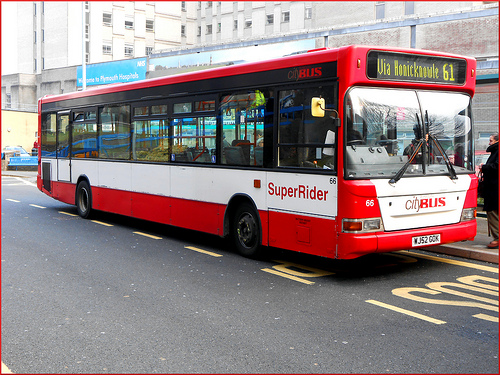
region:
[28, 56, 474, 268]
Large red and white city bus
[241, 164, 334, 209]
Bus has SuperRider printed on side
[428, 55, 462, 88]
Bus number is 61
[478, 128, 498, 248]
Person at bus stop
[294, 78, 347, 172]
Rear view mirror on side of bus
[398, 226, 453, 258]
City bus license plate on front of bus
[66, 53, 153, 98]
Blue and white sign behind bus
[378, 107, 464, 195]
Windshield wipers on bus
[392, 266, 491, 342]
Yellow letters on street for bus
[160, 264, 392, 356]
Black asphalt with yellow lines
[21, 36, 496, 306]
red and white bus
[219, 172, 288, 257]
tire on a bus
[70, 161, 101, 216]
tire on a bus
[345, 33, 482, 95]
sign on a bus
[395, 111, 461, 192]
wipers on a bus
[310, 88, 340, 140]
mirror on a bus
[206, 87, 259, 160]
window on a bus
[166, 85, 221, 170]
window on a bus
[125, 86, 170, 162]
window on a bus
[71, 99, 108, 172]
window on a bus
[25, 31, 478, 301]
this bus is a Super Rider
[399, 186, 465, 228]
it is a city bus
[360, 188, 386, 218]
it has the number 66 on the front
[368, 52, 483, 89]
the writing at the top of the bus is in yellow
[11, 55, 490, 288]
the bus is red & white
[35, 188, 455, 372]
a broken yellow line is painted on the road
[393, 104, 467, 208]
the windshield wipers are very large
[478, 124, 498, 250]
a man in a black coat stands at the front of the bus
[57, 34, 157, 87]
the sign in the background is blue with white letters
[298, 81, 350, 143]
the bus has a big side mirror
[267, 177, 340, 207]
red lettering says SuperRider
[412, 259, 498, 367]
yellow paint spells BUS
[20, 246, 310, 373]
light grey asphalt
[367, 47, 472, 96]
bus sign with yellow lettering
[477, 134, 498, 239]
man in long black coat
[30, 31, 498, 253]
red and white city bus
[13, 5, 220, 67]
tall city building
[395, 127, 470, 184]
grey and red windshield wipers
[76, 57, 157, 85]
bright blue sign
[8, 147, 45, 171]
bright blue bench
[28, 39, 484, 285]
Bus on the road.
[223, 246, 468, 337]
Yellow lines on the road.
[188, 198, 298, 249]
Wheels on the bus.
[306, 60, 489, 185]
Window on the bus.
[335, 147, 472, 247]
Lights on the bus.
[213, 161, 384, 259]
Writing on the bus.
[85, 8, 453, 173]
Buildings behind the bus.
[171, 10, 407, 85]
Windows on the building.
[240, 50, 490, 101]
Destination on the bus.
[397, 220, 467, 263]
License on the bus.